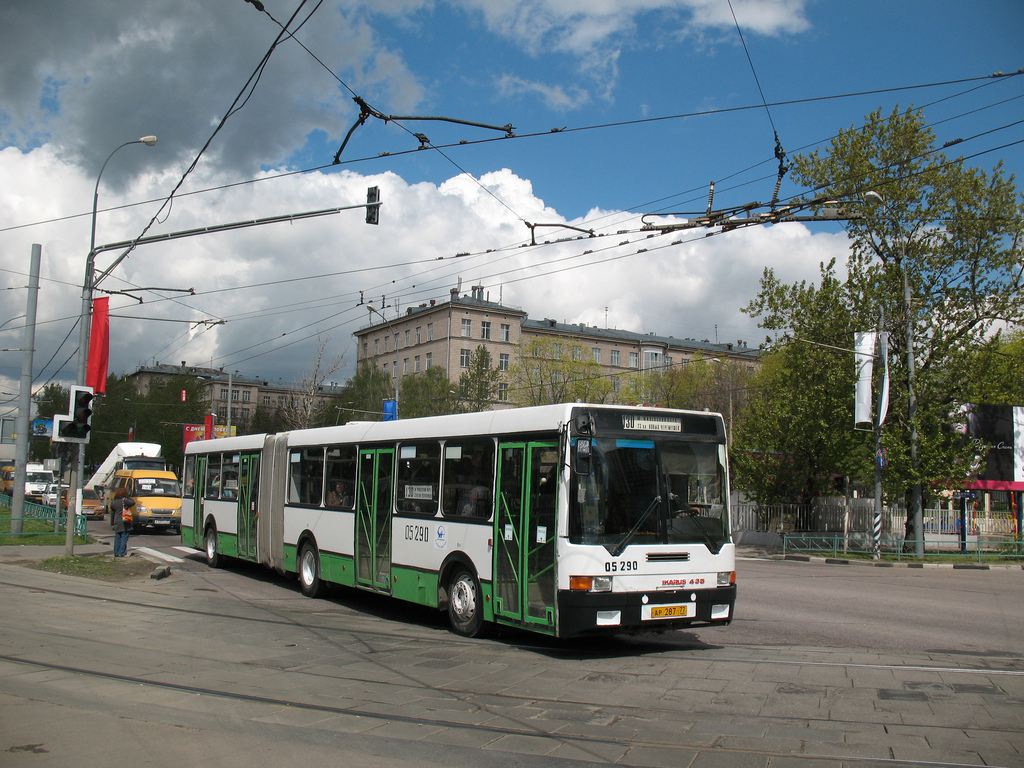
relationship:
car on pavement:
[23, 452, 162, 578] [83, 631, 297, 727]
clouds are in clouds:
[209, 188, 387, 309] [0, 0, 1022, 414]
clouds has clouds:
[0, 0, 1022, 414] [209, 188, 387, 309]